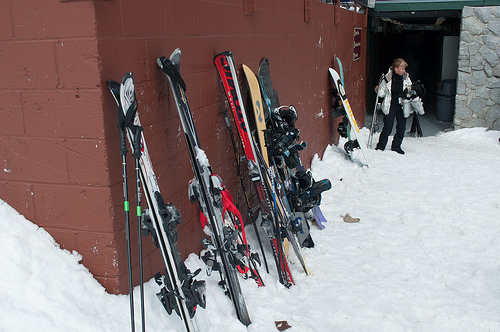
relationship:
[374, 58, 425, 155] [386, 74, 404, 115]
person has shirt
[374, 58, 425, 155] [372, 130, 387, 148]
person has shoe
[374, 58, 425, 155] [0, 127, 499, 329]
person on snow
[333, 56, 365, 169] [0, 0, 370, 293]
skis lean on wall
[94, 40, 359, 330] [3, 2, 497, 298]
skiis against building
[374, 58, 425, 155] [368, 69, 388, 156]
person holding skis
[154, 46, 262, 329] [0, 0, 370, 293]
skis on wall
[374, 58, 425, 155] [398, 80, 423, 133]
person holding skis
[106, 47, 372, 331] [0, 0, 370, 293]
skiis leans on wall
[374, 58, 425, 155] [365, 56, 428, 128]
person wears coat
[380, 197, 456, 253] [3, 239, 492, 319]
snow on ground